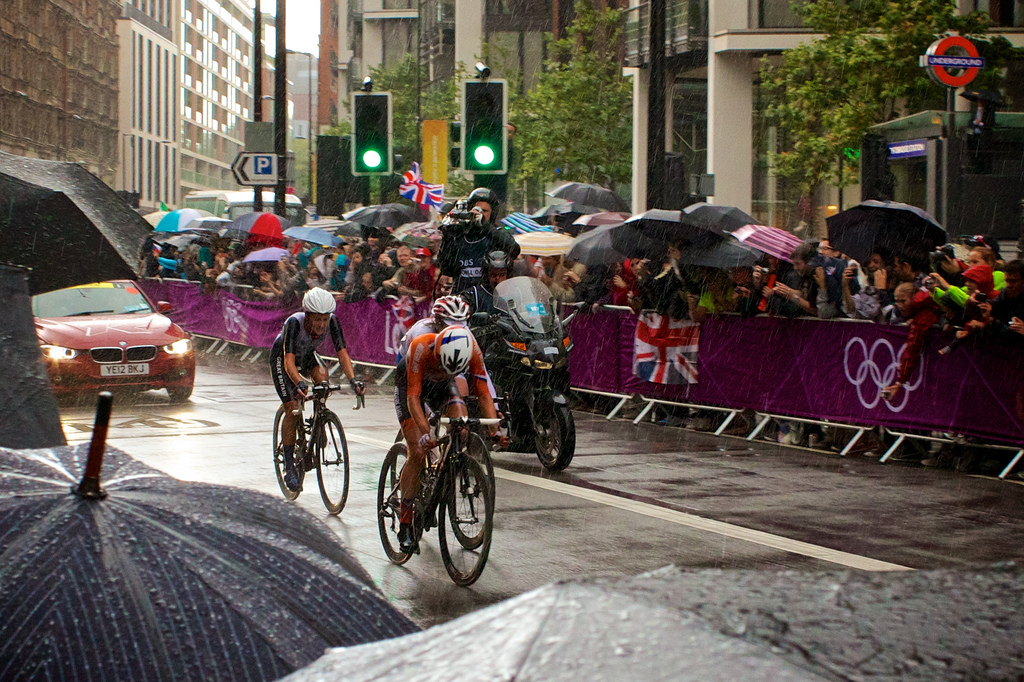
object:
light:
[361, 149, 381, 168]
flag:
[399, 162, 446, 208]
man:
[391, 295, 498, 553]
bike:
[373, 393, 516, 587]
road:
[603, 434, 745, 544]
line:
[607, 474, 687, 535]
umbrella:
[0, 440, 425, 680]